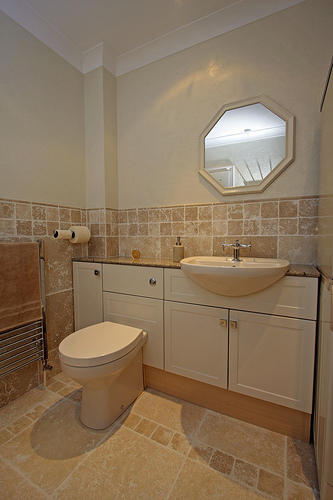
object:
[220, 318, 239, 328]
cupboard handles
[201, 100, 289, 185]
mirror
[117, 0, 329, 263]
wall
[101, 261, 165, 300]
drawer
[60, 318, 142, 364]
toilet seat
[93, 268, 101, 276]
knobs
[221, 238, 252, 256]
faucet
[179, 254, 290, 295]
sink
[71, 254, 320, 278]
counter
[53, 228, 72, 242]
toilet paper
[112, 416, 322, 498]
lines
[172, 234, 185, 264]
lotion dispenser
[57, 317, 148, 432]
toilet bowl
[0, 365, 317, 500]
flooring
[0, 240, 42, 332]
towel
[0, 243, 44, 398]
rack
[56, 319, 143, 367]
lid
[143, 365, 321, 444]
base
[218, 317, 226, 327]
handle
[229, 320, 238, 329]
handle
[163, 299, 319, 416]
cabinet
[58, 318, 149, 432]
toilet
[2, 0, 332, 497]
bathroom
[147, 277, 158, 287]
flush valve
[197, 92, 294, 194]
mirror frame